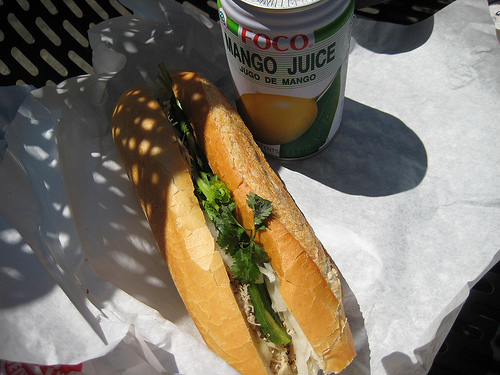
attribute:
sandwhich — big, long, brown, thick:
[122, 68, 327, 354]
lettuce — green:
[212, 206, 273, 280]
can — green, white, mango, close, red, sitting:
[221, 6, 365, 162]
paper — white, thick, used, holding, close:
[39, 176, 135, 340]